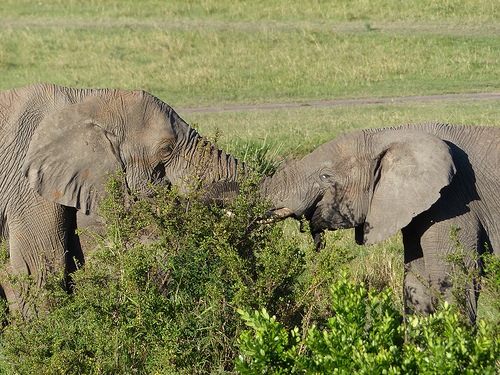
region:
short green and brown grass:
[53, 25, 146, 54]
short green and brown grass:
[116, 27, 209, 65]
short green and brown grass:
[229, 21, 314, 79]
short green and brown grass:
[195, 75, 300, 123]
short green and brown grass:
[312, 7, 413, 92]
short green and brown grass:
[387, 7, 474, 101]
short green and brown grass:
[255, 79, 327, 119]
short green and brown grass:
[65, 12, 176, 82]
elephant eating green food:
[242, 115, 478, 274]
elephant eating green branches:
[14, 81, 249, 264]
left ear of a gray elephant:
[365, 127, 459, 247]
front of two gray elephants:
[5, 52, 491, 364]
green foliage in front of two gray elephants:
[47, 151, 477, 358]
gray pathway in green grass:
[348, 0, 493, 45]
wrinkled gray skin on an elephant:
[2, 82, 44, 226]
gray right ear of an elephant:
[18, 91, 139, 225]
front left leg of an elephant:
[422, 213, 483, 340]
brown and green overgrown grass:
[25, 25, 290, 81]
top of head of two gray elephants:
[100, 65, 370, 147]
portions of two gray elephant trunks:
[172, 123, 311, 225]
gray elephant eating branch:
[258, 120, 489, 308]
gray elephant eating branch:
[27, 86, 277, 262]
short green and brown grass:
[24, 12, 82, 36]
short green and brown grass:
[46, 51, 125, 81]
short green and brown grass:
[117, 14, 181, 44]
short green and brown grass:
[152, 38, 261, 89]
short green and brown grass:
[246, 14, 329, 54]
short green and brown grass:
[242, 45, 321, 123]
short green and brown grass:
[363, 23, 454, 62]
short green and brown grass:
[291, 37, 392, 112]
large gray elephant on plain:
[268, 111, 483, 328]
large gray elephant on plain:
[23, 87, 275, 315]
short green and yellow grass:
[27, 16, 119, 68]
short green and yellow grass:
[60, 54, 123, 77]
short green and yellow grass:
[128, 25, 208, 51]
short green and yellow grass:
[225, 73, 288, 115]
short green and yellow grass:
[304, 78, 389, 125]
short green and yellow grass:
[425, 46, 485, 95]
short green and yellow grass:
[247, 21, 351, 90]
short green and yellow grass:
[360, 13, 453, 98]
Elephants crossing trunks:
[3, 58, 493, 319]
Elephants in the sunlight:
[3, 53, 498, 371]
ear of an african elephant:
[24, 113, 132, 216]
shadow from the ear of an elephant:
[436, 138, 471, 219]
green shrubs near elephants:
[63, 201, 477, 373]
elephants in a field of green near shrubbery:
[13, 23, 495, 361]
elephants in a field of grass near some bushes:
[8, 53, 495, 363]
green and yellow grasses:
[116, 40, 226, 75]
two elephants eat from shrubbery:
[30, 71, 491, 294]